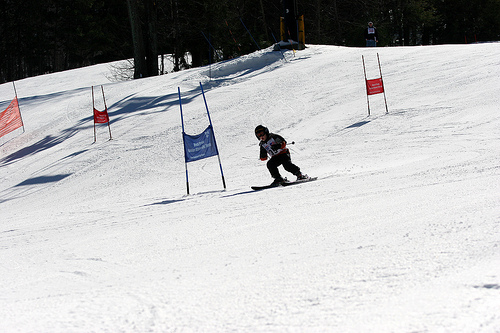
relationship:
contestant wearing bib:
[243, 121, 322, 192] [255, 140, 287, 163]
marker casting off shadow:
[88, 81, 114, 143] [14, 166, 79, 186]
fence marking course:
[2, 78, 27, 137] [0, 40, 480, 331]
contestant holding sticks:
[255, 125, 309, 185] [279, 124, 341, 155]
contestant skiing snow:
[255, 125, 309, 185] [261, 190, 391, 295]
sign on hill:
[182, 126, 216, 161] [408, 42, 498, 299]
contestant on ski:
[255, 125, 309, 185] [250, 157, 312, 188]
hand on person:
[260, 155, 267, 160] [255, 125, 308, 186]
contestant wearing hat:
[255, 125, 309, 185] [255, 123, 268, 136]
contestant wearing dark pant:
[255, 125, 309, 185] [265, 146, 297, 181]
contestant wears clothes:
[255, 125, 309, 185] [256, 133, 301, 180]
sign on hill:
[349, 48, 398, 105] [298, 28, 468, 257]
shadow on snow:
[222, 187, 261, 198] [2, 42, 499, 329]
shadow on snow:
[150, 195, 185, 208] [2, 42, 499, 329]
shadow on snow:
[344, 113, 373, 134] [2, 42, 499, 329]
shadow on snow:
[0, 145, 90, 203] [2, 42, 499, 329]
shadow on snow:
[0, 75, 226, 167] [2, 42, 499, 329]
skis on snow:
[255, 167, 333, 202] [2, 42, 499, 329]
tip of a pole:
[290, 137, 295, 147] [276, 134, 310, 150]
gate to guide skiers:
[83, 95, 130, 135] [237, 91, 302, 198]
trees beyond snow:
[5, 5, 494, 105] [248, 214, 446, 268]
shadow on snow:
[222, 181, 280, 198] [232, 219, 364, 319]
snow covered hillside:
[214, 203, 389, 290] [321, 25, 464, 121]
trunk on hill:
[123, 1, 163, 78] [108, 24, 496, 295]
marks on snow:
[421, 111, 468, 188] [2, 42, 499, 329]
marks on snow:
[343, 241, 385, 258] [2, 42, 499, 329]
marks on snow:
[61, 248, 123, 288] [2, 42, 499, 329]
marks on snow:
[290, 94, 345, 119] [2, 42, 499, 329]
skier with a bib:
[342, 16, 390, 50] [366, 22, 378, 34]